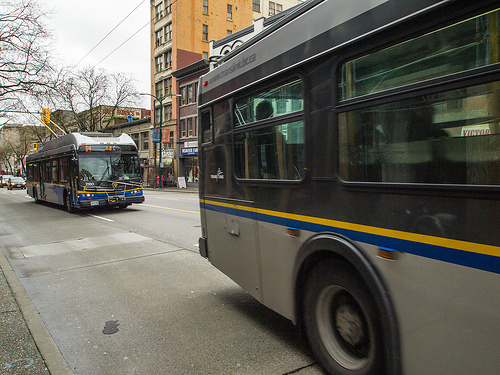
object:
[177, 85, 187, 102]
window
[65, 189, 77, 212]
wheel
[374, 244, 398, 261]
light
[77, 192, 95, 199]
headlights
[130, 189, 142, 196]
headlights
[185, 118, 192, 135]
window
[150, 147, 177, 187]
store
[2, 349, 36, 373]
number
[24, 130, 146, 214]
bus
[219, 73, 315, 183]
window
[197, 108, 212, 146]
window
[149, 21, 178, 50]
window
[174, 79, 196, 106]
window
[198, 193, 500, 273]
stripe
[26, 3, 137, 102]
sky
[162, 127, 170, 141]
sign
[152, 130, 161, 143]
sign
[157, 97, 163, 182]
pole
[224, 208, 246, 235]
gas tank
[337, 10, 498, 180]
window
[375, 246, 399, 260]
reflector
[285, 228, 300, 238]
reflector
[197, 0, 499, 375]
bus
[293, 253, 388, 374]
tire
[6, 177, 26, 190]
car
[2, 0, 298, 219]
background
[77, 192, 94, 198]
reflector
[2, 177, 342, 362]
road